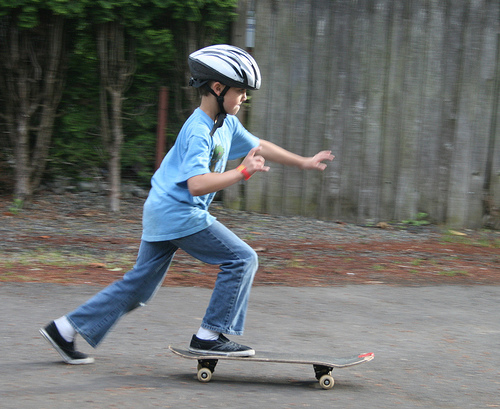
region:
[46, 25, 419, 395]
person riding on a skateboard.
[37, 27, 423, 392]
little person on a skateboard.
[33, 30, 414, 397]
little person with one foot on skateboard.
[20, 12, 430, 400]
little kid on a skateboard.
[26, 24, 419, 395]
person pushing down a path on a skateboard.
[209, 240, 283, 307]
right knee to a person.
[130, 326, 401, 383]
one foot on a skateboard.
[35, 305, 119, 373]
black shoe planted on pavement.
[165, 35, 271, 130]
person wearing a helmet for protection.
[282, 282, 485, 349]
cement pavement in view.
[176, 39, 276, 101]
a white and black helmet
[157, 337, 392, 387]
a black skate board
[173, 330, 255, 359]
a black slip on shoe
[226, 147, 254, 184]
a red plastic wrist band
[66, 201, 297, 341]
a pair of blue jeans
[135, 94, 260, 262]
a pale blue shirt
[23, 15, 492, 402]
a boy on his skateboard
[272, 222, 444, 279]
dirt and gravel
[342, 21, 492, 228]
a wooden fence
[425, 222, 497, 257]
some small tufts of grass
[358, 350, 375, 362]
tip of skateboard is red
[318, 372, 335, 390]
gray wheel under skateboard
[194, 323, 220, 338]
boy wearing white socks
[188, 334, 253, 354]
boy wearing black slip on shoes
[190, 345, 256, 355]
sole of shoe is white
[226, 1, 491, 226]
wood fence behind boy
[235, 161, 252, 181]
orange band on wrist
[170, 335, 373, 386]
skateboard on pavement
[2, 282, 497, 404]
pavement is gray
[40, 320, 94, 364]
the ball of the boy's foot is touching the pavement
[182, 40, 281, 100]
the helmet is silver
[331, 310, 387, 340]
the ground is gray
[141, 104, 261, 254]
the shirt is blue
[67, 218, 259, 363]
the pants are blue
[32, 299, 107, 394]
the shoe is black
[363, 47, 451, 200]
the fence is wooden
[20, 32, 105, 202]
the trunk is brown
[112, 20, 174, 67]
the leaves are green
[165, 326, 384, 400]
the skateboard is black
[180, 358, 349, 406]
the wheels are round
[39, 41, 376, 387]
a tyke on a skateboard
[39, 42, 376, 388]
little guy on a skateboard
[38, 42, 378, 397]
a boy on a skateboard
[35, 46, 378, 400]
a kid on a skateboard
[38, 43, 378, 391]
someone's son on a skateboard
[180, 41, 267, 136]
boy with a helmet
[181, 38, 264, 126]
skateboarder with a helmet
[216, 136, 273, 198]
hand with finger in the air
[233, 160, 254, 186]
something orange on the wrist